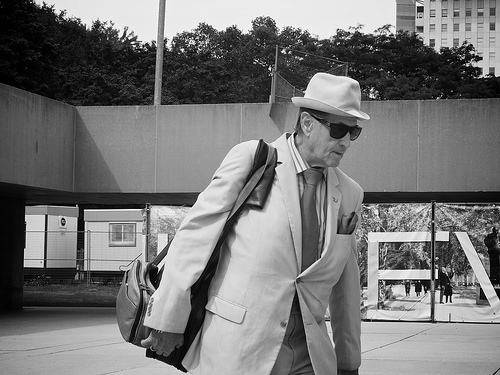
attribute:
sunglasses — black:
[312, 114, 363, 143]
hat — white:
[291, 71, 370, 122]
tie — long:
[301, 168, 323, 270]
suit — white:
[142, 132, 361, 374]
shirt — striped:
[285, 132, 327, 263]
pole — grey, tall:
[153, 1, 166, 105]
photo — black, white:
[0, 1, 499, 375]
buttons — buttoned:
[293, 278, 303, 285]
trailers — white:
[25, 207, 149, 273]